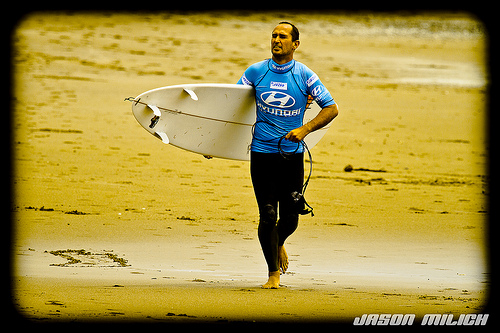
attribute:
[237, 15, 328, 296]
surfer — running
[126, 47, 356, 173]
board — surf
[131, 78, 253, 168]
surfboard — white, long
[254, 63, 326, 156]
shirt — swim, white, blue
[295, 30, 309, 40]
hair — short, cut, black, man's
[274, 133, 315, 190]
cord — LONG, BLACK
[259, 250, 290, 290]
shoes — no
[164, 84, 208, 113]
fin — white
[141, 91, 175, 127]
fin — white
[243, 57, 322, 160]
shirt — blue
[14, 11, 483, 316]
sand — orange colored, Yellow, tan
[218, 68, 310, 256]
wetsuit — black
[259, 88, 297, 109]
logo — white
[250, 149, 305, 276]
wetsuit pants — black 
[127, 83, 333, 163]
surfboard — white